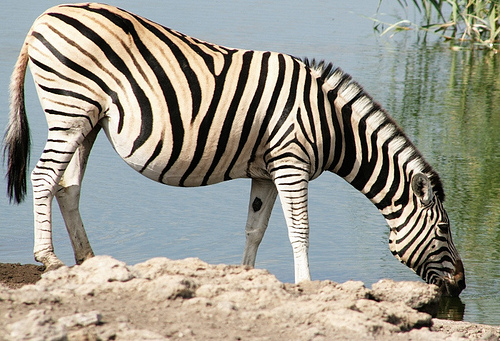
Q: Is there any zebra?
A: Yes, there is a zebra.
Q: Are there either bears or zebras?
A: Yes, there is a zebra.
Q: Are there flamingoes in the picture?
A: No, there are no flamingoes.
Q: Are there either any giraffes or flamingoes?
A: No, there are no flamingoes or giraffes.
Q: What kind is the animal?
A: The animal is a zebra.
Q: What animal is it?
A: The animal is a zebra.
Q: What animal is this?
A: This is a zebra.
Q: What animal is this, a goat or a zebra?
A: This is a zebra.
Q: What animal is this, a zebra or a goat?
A: This is a zebra.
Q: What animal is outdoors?
A: The animal is a zebra.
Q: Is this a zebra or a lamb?
A: This is a zebra.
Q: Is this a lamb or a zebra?
A: This is a zebra.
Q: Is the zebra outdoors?
A: Yes, the zebra is outdoors.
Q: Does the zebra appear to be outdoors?
A: Yes, the zebra is outdoors.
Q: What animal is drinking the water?
A: The zebra is drinking the water.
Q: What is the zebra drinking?
A: The zebra is drinking water.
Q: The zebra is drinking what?
A: The zebra is drinking water.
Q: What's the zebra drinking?
A: The zebra is drinking water.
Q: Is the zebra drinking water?
A: Yes, the zebra is drinking water.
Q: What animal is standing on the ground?
A: The zebra is standing on the ground.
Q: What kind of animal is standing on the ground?
A: The animal is a zebra.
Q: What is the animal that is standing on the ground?
A: The animal is a zebra.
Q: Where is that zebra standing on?
A: The zebra is standing on the ground.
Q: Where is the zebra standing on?
A: The zebra is standing on the ground.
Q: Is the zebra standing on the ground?
A: Yes, the zebra is standing on the ground.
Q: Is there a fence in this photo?
A: No, there are no fences.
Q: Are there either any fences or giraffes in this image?
A: No, there are no fences or giraffes.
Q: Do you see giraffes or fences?
A: No, there are no fences or giraffes.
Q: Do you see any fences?
A: No, there are no fences.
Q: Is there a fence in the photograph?
A: No, there are no fences.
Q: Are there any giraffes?
A: No, there are no giraffes.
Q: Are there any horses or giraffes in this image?
A: No, there are no giraffes or horses.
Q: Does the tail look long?
A: Yes, the tail is long.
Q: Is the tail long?
A: Yes, the tail is long.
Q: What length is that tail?
A: The tail is long.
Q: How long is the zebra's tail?
A: The tail is long.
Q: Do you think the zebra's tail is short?
A: No, the tail is long.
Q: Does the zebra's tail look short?
A: No, the tail is long.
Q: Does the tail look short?
A: No, the tail is long.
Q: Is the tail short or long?
A: The tail is long.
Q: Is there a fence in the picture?
A: No, there are no fences.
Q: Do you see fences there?
A: No, there are no fences.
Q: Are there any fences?
A: No, there are no fences.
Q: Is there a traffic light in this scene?
A: No, there are no traffic lights.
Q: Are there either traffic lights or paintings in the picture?
A: No, there are no traffic lights or paintings.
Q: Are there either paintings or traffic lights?
A: No, there are no traffic lights or paintings.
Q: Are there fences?
A: No, there are no fences.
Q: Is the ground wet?
A: Yes, the ground is wet.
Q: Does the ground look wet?
A: Yes, the ground is wet.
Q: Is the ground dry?
A: No, the ground is wet.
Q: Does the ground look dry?
A: No, the ground is wet.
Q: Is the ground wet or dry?
A: The ground is wet.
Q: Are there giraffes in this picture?
A: No, there are no giraffes.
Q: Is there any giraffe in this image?
A: No, there are no giraffes.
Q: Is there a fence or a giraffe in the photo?
A: No, there are no giraffes or fences.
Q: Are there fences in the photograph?
A: No, there are no fences.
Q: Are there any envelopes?
A: No, there are no envelopes.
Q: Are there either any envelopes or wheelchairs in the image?
A: No, there are no envelopes or wheelchairs.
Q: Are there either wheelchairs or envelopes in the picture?
A: No, there are no envelopes or wheelchairs.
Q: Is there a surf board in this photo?
A: No, there are no surfboards.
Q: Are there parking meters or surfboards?
A: No, there are no surfboards or parking meters.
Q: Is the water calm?
A: Yes, the water is calm.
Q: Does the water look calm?
A: Yes, the water is calm.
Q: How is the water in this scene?
A: The water is calm.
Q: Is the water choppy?
A: No, the water is calm.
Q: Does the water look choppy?
A: No, the water is calm.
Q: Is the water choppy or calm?
A: The water is calm.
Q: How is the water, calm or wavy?
A: The water is calm.